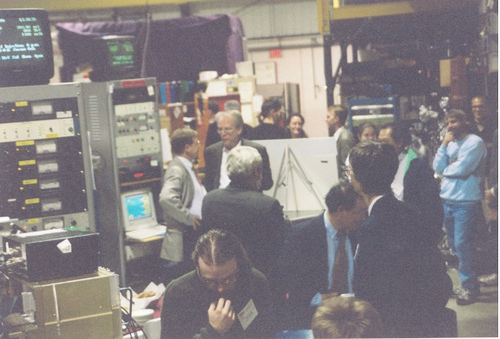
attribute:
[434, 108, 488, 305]
person — standing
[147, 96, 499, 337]
people — group, standing, talking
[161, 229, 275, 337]
man — standing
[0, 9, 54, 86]
tv — on, small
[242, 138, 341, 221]
board — white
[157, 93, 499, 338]
men — wearing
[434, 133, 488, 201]
sweater — blue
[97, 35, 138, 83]
screen — computer, television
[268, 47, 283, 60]
sign — red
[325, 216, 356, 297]
shirt — blue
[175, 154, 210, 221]
shirt — white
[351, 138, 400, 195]
hair — brown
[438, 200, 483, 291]
jeans — blue